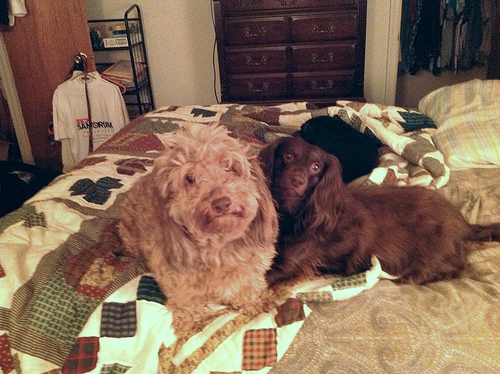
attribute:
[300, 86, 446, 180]
quilt — plaid, colorful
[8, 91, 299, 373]
dog — fluffy, staring, cream, fury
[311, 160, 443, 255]
hair — brown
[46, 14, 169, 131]
stand — metal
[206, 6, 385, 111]
dresser — wood, drawers, brown, wooden, black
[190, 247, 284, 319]
fur — white, brown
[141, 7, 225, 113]
wall — white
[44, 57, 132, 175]
shirt — white, clothese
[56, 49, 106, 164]
belt — brown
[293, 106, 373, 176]
sweater — black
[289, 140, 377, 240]
ear — long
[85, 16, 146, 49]
cupboards — closed, white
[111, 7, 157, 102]
wire — black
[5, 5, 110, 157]
frame — wood